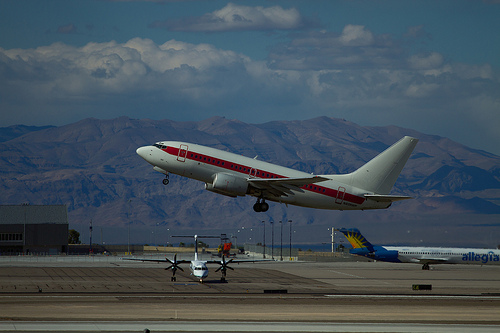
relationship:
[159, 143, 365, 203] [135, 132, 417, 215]
stripe on airplane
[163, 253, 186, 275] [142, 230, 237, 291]
propeller on airplane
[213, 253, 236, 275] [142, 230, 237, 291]
propeller on airplane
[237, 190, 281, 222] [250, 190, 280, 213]
tires of landing gear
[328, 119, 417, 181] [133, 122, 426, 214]
white tail of airplane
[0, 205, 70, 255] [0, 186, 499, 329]
building at airport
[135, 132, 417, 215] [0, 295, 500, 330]
airplane from runway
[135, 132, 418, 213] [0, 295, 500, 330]
airplane out to runway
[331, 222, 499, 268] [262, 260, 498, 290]
airplane on tarmac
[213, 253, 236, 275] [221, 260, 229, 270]
propeller of engine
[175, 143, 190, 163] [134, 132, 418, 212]
door on plane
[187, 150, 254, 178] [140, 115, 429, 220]
windows on plane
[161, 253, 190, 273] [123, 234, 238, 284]
propeller on airplane